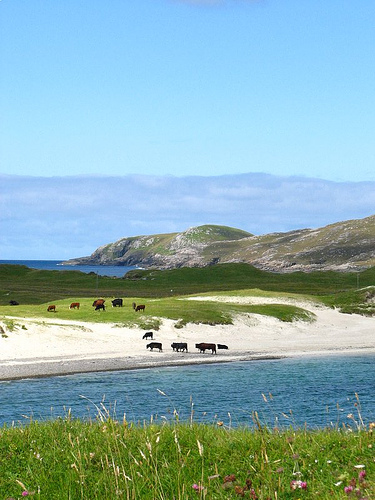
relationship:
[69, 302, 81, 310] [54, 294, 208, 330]
animal grazing on grass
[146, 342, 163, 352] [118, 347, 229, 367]
animal on sand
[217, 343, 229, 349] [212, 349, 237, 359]
animal laying in sand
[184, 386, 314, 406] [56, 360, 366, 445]
ripples in water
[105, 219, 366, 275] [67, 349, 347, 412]
mountains between water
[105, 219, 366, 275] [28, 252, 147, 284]
mountains between water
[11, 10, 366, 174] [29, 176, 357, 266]
sky above mountain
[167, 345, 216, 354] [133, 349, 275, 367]
shadow on sand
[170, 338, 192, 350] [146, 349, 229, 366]
animal on sand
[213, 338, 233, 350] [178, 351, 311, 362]
animal laying on sand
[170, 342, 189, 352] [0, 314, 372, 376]
animal standing on sand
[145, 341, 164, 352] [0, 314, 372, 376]
animal standing on sand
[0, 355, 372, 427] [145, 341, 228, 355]
water in front of animals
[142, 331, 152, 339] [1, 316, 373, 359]
animal standing on sand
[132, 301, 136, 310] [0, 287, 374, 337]
animal standing in grass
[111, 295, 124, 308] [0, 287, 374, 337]
animal standing in grass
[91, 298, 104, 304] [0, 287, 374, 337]
animal standing in grass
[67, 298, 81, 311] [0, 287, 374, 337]
animal standing in grass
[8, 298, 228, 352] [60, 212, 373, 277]
cattle walking across mountains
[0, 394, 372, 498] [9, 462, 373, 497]
grass with flowers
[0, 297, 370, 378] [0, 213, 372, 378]
beaches on mountain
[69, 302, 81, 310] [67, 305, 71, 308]
animal with head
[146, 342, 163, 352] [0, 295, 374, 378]
animal walking on beach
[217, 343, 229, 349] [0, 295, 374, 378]
animal sitting on beach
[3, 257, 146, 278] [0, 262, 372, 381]
water on other side of island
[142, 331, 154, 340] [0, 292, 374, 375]
animal standing in sand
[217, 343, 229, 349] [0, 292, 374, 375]
animal laying in sand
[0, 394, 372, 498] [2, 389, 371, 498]
grass with plants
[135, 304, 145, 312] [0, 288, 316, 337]
cow grazing in grass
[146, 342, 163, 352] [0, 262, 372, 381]
animal on island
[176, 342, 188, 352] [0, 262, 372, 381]
animal on island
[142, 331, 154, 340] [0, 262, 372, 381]
animal on island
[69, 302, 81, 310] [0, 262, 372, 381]
animal on island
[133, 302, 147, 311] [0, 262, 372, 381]
cow on island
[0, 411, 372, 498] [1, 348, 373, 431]
grass on side of water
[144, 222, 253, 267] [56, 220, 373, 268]
hill on island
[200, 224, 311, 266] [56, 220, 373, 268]
hill on island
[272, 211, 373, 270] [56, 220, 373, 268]
hill on island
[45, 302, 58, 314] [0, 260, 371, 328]
cow in grass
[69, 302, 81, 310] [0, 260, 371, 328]
animal in grass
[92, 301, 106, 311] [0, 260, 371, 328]
cow in grass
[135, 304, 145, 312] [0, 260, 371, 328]
cow in grass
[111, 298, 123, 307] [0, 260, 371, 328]
animal in grass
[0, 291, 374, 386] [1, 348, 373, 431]
sand near water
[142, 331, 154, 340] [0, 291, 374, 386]
animal on sand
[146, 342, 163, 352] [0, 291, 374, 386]
animal on sand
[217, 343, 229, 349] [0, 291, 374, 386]
animal on sand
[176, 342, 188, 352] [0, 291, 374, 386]
animal on sand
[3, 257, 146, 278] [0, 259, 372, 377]
water next to land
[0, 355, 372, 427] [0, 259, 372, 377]
water next to land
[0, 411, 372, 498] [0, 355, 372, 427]
grass next to water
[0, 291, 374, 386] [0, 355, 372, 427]
sand next to water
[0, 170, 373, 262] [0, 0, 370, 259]
cloud in sky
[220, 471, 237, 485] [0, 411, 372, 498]
flower in grass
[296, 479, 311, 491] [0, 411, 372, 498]
flower in grass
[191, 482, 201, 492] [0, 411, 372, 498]
flower in grass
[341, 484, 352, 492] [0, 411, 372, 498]
flower in grass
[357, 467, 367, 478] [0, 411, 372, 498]
flower in grass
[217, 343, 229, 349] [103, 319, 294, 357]
animal focused shore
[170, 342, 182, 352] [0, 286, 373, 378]
animal standing on stand